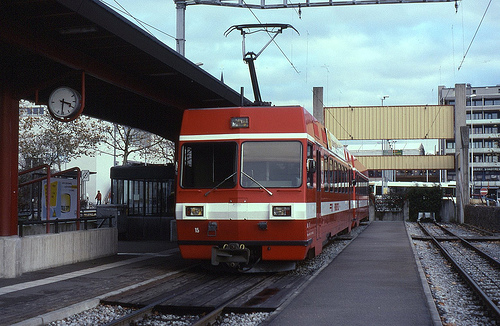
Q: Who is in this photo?
A: No one.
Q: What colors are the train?
A: Red and white.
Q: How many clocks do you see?
A: One.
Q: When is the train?
A: On the tracks.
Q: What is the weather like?
A: Cloudy.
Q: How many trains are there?
A: One.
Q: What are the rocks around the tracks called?
A: Gravel.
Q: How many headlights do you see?
A: 2.